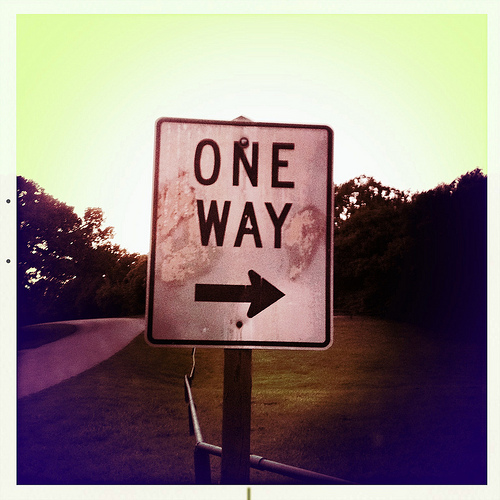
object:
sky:
[17, 15, 491, 289]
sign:
[142, 116, 335, 353]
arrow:
[192, 268, 287, 319]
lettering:
[193, 138, 295, 248]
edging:
[144, 115, 334, 352]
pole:
[217, 348, 252, 484]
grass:
[16, 316, 487, 487]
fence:
[183, 346, 357, 484]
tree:
[18, 172, 89, 323]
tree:
[95, 283, 137, 317]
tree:
[336, 169, 410, 237]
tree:
[336, 198, 402, 320]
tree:
[409, 165, 487, 327]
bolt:
[236, 321, 244, 329]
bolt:
[239, 136, 249, 148]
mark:
[157, 168, 220, 292]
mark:
[280, 202, 325, 282]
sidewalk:
[17, 317, 145, 399]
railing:
[182, 371, 204, 446]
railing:
[202, 441, 343, 484]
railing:
[186, 346, 198, 382]